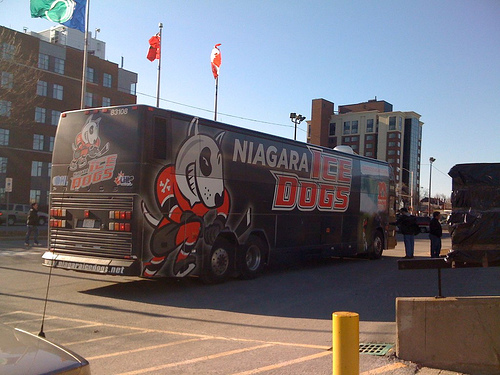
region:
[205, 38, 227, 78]
Flag with red and white design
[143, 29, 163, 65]
Red flag flying in the breeze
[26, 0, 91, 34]
Blue, green, and white flag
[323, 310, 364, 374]
Yellow safety post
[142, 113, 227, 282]
Drawing of dog mascot on side of bus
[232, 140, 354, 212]
Words "Niagara Ice Dogs" on side of bus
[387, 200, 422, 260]
Man getting on bus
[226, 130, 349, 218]
Black bus with red and white lettering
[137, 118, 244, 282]
Dog mascot wearing red and black uniform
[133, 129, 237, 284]
Mascot of dog playing hockey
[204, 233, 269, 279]
The back bus wheels are black.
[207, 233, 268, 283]
The back bus wheels are round.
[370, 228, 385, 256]
The front wheel is round.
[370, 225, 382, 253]
The front wheel is black.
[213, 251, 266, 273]
The back hub caps are silver.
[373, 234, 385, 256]
The front hub cap is silver.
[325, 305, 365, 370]
The pole in the forefront is yellow.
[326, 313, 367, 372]
The pole in the forefront is made from metal.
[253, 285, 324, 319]
The pavement is black.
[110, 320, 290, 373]
The pavement has yellow stripes.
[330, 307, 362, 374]
A thick yellow pole.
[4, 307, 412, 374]
Yellow lines on the street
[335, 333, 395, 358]
A storm drain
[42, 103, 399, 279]
A black bus with decals on it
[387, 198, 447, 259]
Two people standing by a bus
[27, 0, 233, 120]
Flags hung on flag poles.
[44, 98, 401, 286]
A parked bus.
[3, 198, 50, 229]
An SUV.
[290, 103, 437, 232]
Parking lot lights.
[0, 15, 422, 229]
Large buildings.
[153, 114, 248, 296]
cartoon of a dog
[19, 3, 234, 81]
three flags on poles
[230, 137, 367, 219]
NIAGARA ICE DOGS on side of bus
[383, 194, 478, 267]
people standing outside the bus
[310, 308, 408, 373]
yellow pole next to crosswalk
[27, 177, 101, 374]
car antenna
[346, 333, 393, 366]
grate next to walkway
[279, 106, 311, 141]
two street lights on one pole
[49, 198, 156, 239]
back lights on the bus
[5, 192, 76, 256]
man on other side of bus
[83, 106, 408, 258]
tour bus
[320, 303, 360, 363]
yellow post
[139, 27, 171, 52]
red colored flag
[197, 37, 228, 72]
white and red colored flag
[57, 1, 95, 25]
blue and white flag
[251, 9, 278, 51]
white clouds in blue sky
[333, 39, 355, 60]
white clouds in blue sky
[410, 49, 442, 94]
white clouds in blue sky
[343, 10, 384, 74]
white clouds in blue sky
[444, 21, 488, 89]
white clouds in blue sky